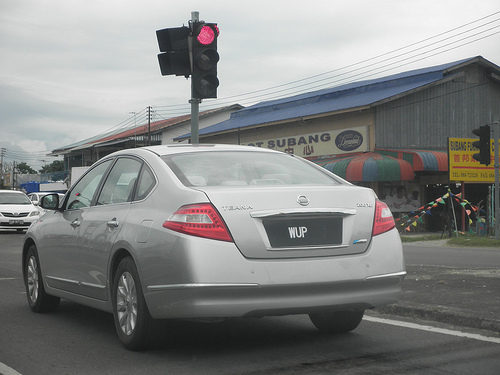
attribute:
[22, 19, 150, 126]
sky — bright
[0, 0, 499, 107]
sky — blue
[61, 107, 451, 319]
car — grey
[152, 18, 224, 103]
traffic light — red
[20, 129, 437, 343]
car — silver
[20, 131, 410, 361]
car — silver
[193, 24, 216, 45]
light — red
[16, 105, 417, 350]
car — stopped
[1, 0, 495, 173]
clouds — white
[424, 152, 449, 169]
awning — red, blue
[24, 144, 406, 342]
car — brand new, stopped, silver, white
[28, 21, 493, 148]
sky — blue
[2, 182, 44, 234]
car — white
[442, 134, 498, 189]
sign — yellow